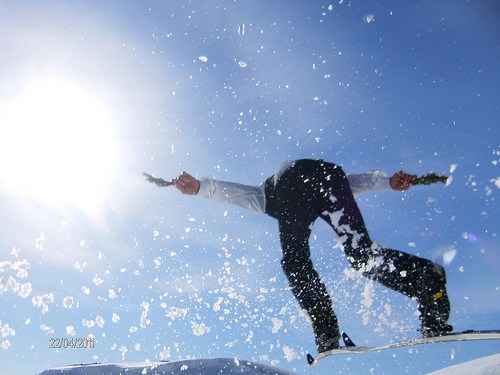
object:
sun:
[3, 75, 140, 227]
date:
[49, 336, 96, 349]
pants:
[275, 158, 433, 344]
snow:
[118, 247, 259, 320]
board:
[305, 329, 499, 368]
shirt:
[194, 159, 393, 214]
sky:
[145, 26, 431, 101]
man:
[170, 158, 452, 354]